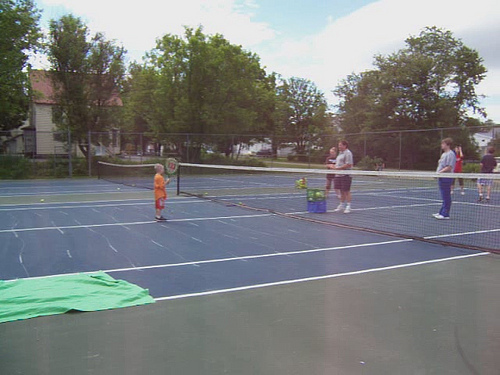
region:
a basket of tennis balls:
[299, 179, 338, 218]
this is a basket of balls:
[297, 180, 330, 204]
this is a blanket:
[1, 264, 164, 325]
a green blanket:
[1, 250, 165, 319]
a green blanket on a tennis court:
[2, 266, 184, 337]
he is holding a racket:
[137, 123, 194, 223]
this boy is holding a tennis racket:
[135, 140, 202, 224]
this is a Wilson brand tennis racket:
[160, 148, 188, 190]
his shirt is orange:
[141, 157, 179, 198]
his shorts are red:
[147, 192, 179, 214]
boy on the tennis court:
[151, 163, 167, 223]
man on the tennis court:
[332, 138, 359, 220]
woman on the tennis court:
[432, 137, 452, 219]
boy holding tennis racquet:
[164, 156, 178, 181]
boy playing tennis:
[150, 154, 183, 221]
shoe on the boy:
[156, 214, 161, 219]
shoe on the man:
[346, 205, 352, 215]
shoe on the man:
[332, 204, 343, 210]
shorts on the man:
[333, 172, 352, 187]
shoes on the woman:
[433, 214, 447, 216]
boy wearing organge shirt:
[135, 161, 225, 246]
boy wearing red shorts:
[145, 150, 185, 240]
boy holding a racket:
[145, 145, 185, 235]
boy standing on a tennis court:
[141, 148, 208, 226]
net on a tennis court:
[205, 150, 265, 201]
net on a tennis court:
[97, 161, 148, 206]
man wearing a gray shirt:
[423, 131, 463, 232]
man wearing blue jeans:
[431, 125, 461, 236]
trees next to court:
[151, 42, 231, 124]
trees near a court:
[381, 54, 438, 104]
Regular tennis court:
[1, 176, 498, 281]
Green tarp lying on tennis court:
[0, 274, 167, 319]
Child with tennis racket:
[148, 151, 188, 220]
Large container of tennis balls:
[300, 187, 340, 212]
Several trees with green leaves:
[2, 0, 480, 205]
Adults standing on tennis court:
[315, 119, 496, 241]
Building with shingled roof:
[20, 54, 134, 167]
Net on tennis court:
[173, 150, 499, 275]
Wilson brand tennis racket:
[164, 152, 184, 189]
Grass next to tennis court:
[2, 145, 264, 173]